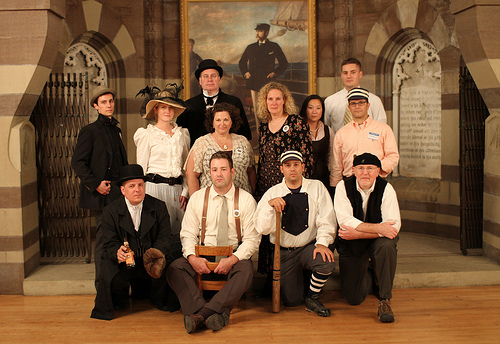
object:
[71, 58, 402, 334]
group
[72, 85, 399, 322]
clothes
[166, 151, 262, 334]
man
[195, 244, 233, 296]
chair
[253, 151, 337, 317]
man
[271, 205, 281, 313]
bat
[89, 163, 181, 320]
man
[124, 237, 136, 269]
beer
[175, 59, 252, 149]
man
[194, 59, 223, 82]
hat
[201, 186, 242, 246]
suspenders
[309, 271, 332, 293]
socks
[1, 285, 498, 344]
floor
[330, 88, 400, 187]
man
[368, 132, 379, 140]
name tag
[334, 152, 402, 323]
man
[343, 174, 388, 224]
vest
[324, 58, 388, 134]
man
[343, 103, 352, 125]
tie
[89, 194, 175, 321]
coat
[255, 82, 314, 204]
woman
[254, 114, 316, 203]
dress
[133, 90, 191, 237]
woman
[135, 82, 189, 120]
hat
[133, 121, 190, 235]
dress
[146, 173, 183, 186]
belt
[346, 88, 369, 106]
hat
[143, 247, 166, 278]
glove